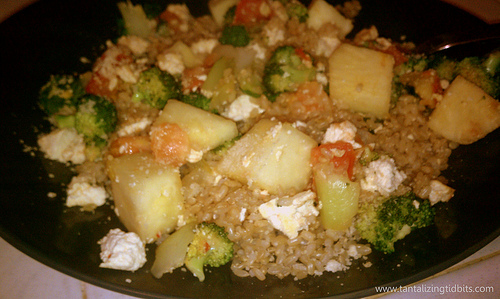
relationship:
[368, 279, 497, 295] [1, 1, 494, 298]
logo near plate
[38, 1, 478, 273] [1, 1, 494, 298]
food on plate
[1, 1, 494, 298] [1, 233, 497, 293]
plate on cloth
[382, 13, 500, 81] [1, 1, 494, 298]
spoon in plate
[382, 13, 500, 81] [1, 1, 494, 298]
spoon on plate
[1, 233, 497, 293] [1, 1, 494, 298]
cloth under plate